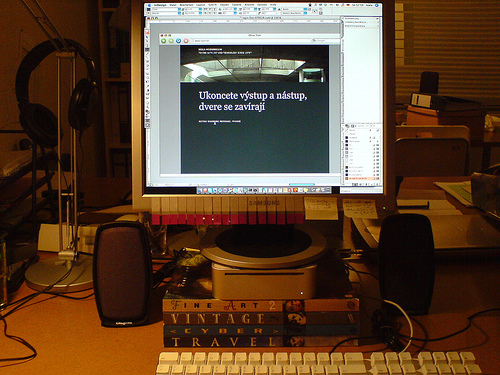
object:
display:
[181, 83, 330, 174]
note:
[343, 199, 378, 220]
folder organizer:
[393, 125, 469, 176]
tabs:
[168, 195, 178, 224]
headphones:
[13, 37, 105, 148]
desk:
[2, 0, 499, 375]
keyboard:
[154, 350, 484, 373]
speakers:
[377, 214, 427, 295]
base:
[200, 224, 329, 269]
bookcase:
[83, 6, 127, 207]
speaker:
[91, 220, 153, 328]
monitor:
[131, 0, 395, 212]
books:
[161, 310, 361, 325]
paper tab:
[151, 197, 160, 225]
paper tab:
[161, 198, 170, 226]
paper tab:
[177, 195, 186, 224]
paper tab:
[221, 196, 229, 225]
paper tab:
[257, 195, 267, 224]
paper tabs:
[294, 196, 304, 224]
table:
[1, 250, 498, 372]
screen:
[130, 0, 396, 213]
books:
[160, 299, 361, 313]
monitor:
[124, 9, 398, 225]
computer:
[130, 0, 387, 270]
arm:
[20, 0, 81, 270]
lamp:
[18, 0, 94, 293]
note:
[304, 195, 339, 219]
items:
[92, 213, 439, 349]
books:
[161, 336, 357, 347]